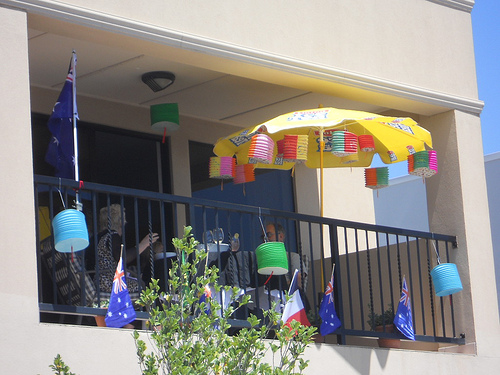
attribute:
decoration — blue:
[51, 208, 89, 261]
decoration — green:
[256, 225, 301, 280]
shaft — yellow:
[316, 126, 326, 294]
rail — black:
[35, 174, 463, 348]